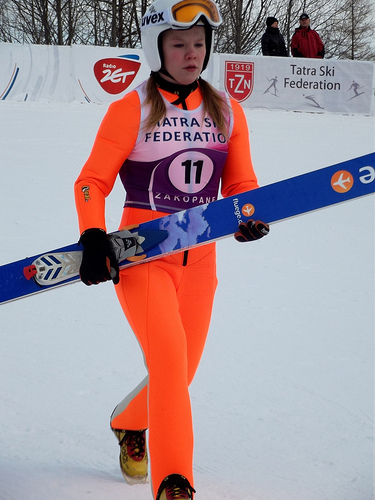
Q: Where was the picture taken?
A: A ski slope.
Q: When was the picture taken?
A: Daytime.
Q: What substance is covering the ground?
A: Snow.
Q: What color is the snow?
A: White.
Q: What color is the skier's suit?
A: Orange.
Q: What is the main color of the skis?
A: Blue.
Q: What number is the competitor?
A: 11.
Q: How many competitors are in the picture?
A: One.